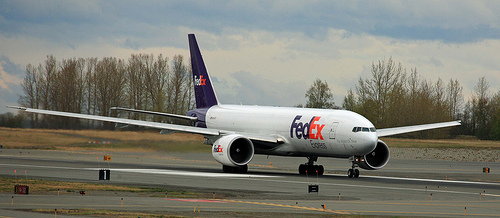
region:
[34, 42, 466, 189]
The airplane is landing.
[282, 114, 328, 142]
The name of the company is FedEx.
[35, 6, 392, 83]
The weather is cloudy.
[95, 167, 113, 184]
The sign reads "one"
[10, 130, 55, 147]
The grass is brown.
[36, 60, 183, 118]
No leaves on the trees.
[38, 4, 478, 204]
It is daytime outside.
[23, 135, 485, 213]
This is a runway.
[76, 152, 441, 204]
runway is also known as the tarmac.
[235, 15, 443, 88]
The clouds are grey and white.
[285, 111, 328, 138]
logo of a company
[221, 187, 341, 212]
lines on a landing strip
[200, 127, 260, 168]
engine of a plane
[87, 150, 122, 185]
orange flags and marker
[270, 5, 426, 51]
an overcast sky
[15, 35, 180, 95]
a row of trees at the horizon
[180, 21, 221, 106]
tall, blue tail of a plane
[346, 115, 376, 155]
cockpit windows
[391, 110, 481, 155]
wing of a plane and landscape beyond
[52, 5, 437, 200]
a FedEx plane taxis on a runway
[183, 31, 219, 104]
Blue tailwing of airplane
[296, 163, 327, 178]
Group of small wheels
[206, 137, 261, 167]
Large white airplane engine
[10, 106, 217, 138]
Long white wing of airplane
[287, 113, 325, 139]
Large FedEx logo on airplane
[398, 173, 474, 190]
Long white safety line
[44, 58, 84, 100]
Group of brown trees without leaves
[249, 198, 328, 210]
Yellow caution line on runway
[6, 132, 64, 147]
Brown dead grass on ground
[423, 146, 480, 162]
Large amounts of grey rocks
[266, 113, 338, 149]
FedEx logo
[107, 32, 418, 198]
an airplane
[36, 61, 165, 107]
tree branches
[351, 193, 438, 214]
The roadway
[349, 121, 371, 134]
windshield of the airplane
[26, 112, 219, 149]
right wing of airplane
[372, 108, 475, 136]
left wing of airplane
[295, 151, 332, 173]
wheels of the airplane.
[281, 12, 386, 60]
the cloudy sky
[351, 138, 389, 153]
the nose of the airplane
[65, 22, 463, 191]
picture taken during the day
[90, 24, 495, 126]
picture taken outdoors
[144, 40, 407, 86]
it is a slightly cloudy day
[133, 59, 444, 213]
a picture of a plane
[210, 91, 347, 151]
the plane is from Fedex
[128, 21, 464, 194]
the body of the plane is white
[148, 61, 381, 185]
the plane is on the tarmac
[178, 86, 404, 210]
the plane has two engines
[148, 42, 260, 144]
the tail of the plane has fedex on it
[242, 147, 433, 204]
the wheels of the plane are on the ground